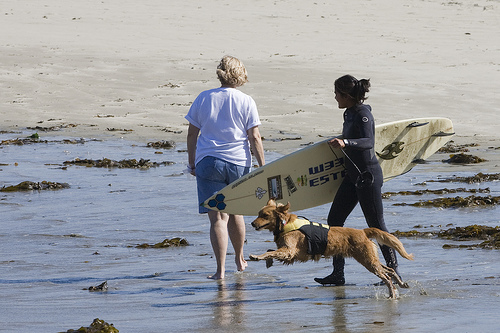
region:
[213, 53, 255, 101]
Person has blonde hair.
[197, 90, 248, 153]
Person wearing white shirt.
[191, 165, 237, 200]
Person wearing blue shorts.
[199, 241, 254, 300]
Person walking on beach barefoot.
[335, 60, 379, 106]
Person has black hair.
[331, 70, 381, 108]
Person has hair pulled back in bun.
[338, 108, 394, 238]
Person wearing wet suit.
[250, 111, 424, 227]
Person carrying white surfboard.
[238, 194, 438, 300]
Brown dog running on beach.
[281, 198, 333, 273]
Dog wearing black and yellow vest.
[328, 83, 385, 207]
A lady carrying a surfboard.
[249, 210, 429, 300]
Dog running on the beach.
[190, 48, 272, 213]
A lady in front of the surfboard.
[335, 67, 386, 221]
The lady is wearing a black wetsuit.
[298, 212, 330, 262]
The dog is wearing a life jacket.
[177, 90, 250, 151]
The person is wearing a white shirt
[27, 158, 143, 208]
Seaweed on the beach.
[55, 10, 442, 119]
Sand on the beach.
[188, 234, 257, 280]
The woman is barefoot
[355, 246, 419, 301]
The dog legs are wet.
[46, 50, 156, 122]
extremely stormy seas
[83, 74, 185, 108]
debris floating in the sea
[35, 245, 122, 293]
wet dirt on the sand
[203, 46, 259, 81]
silver hair on head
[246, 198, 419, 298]
dog jumping on the sand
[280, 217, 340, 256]
blue jacket over dog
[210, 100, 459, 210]
large white surf board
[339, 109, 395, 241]
woman wearing black surf suit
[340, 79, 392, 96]
woman with pony tail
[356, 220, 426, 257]
dog with bushy tail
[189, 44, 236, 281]
WOMAN IN SHALLOW WATER ON BEACH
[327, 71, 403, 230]
WOMAN IN SHALLOW WATER ON BEACH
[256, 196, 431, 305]
DOG RUNNING ALONG BEACH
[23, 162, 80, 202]
SEAWEED LAYING ON SAND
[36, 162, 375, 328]
SHALLOW WATER ON SAND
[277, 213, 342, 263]
BLACK OUTFIT ON DOG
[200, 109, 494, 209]
CREAM COLORED SURFBOARD IN HAND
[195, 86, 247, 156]
WHITE T SHIRT ON WOMAN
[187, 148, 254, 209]
BLUE JEAN SHORTS ON WOMAN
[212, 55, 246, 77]
BLONDE HAIR ON WOMAN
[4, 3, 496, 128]
gray sand on beach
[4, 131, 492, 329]
sand covered in water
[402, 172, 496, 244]
piles of seaweed on sand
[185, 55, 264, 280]
back of walking woman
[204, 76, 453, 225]
woman holding surfboard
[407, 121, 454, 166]
fins on bottom of surfboard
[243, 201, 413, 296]
dog running in water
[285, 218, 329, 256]
yellow and black vest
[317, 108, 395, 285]
black wetsuit on woman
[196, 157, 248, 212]
denim shorts on woman